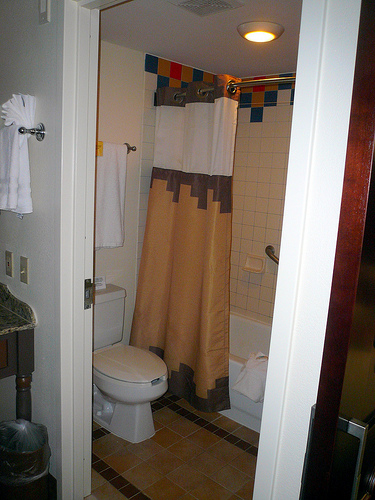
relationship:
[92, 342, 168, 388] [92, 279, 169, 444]
toilet seat on toilet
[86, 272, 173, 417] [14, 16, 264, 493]
toilet in bathroom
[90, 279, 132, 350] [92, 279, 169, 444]
water closet of toilet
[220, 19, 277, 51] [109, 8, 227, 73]
light fixture on ceiling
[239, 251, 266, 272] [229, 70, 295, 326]
soap dish on wall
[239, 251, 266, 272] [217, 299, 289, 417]
soap dish over bath tub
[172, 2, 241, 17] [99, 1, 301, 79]
vent on ceiling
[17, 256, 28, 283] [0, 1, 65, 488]
light switch on wall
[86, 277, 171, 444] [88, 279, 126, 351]
toilet has water closet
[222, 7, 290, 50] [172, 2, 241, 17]
bathroom light has vent